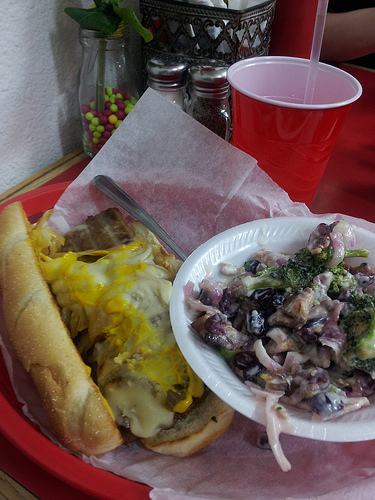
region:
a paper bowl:
[207, 367, 237, 395]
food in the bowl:
[225, 267, 363, 376]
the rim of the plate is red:
[91, 470, 121, 494]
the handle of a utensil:
[97, 174, 153, 208]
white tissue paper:
[133, 128, 200, 183]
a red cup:
[255, 116, 327, 164]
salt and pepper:
[154, 59, 218, 92]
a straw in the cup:
[305, 1, 329, 55]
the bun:
[181, 419, 216, 445]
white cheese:
[116, 390, 153, 420]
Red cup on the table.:
[218, 55, 373, 216]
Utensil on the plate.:
[88, 168, 218, 283]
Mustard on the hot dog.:
[60, 222, 225, 433]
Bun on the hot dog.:
[0, 202, 140, 461]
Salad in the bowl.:
[206, 211, 351, 398]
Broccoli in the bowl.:
[272, 246, 359, 303]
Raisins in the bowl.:
[210, 240, 320, 361]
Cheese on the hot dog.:
[97, 352, 188, 449]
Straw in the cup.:
[297, 8, 345, 108]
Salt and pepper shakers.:
[157, 43, 236, 154]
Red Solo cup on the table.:
[207, 73, 364, 193]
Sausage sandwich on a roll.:
[52, 201, 190, 381]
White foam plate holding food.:
[160, 216, 346, 406]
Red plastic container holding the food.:
[19, 174, 79, 219]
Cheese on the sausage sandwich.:
[120, 250, 163, 315]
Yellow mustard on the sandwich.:
[96, 271, 144, 362]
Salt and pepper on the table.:
[145, 64, 228, 106]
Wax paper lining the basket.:
[92, 99, 203, 192]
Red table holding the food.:
[336, 108, 366, 199]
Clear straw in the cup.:
[293, 1, 333, 108]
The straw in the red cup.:
[306, 0, 321, 101]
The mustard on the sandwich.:
[56, 245, 191, 405]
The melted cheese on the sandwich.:
[50, 245, 192, 423]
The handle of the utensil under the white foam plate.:
[86, 172, 187, 262]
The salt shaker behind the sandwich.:
[147, 54, 186, 110]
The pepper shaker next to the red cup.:
[183, 57, 230, 135]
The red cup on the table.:
[223, 41, 363, 210]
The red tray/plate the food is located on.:
[1, 400, 370, 498]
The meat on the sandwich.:
[52, 215, 188, 429]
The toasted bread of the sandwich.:
[6, 196, 204, 472]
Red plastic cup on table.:
[222, 55, 366, 213]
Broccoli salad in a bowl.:
[169, 211, 374, 444]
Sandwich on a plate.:
[0, 194, 241, 461]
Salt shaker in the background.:
[140, 51, 186, 109]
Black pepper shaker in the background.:
[187, 56, 230, 141]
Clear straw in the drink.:
[304, 1, 329, 104]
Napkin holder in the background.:
[151, 1, 274, 66]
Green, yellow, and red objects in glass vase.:
[77, 79, 138, 154]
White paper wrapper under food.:
[3, 85, 373, 498]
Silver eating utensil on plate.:
[88, 170, 191, 260]